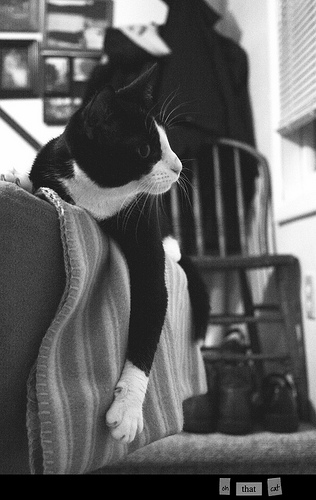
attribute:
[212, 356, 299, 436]
boots — new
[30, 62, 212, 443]
cat — pondering, pictured, black, sitting, lying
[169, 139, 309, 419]
chair — wooden, brown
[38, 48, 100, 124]
picture — hanging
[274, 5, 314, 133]
blinds — white, mini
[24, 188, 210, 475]
blanket — wool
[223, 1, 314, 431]
wall — white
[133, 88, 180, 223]
whiskers — white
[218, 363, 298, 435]
shoes — black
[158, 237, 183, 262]
leg — white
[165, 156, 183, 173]
nose — small